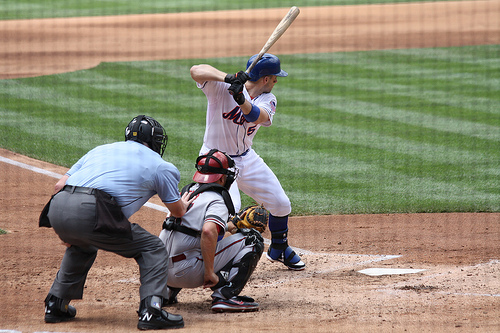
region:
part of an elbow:
[201, 230, 213, 246]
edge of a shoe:
[223, 265, 232, 276]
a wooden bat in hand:
[206, 0, 305, 100]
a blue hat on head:
[223, 40, 295, 86]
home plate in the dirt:
[311, 233, 445, 326]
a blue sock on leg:
[264, 182, 326, 279]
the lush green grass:
[281, 75, 426, 200]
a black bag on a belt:
[85, 183, 140, 245]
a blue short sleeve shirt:
[38, 140, 203, 215]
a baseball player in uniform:
[167, 18, 320, 229]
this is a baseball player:
[145, 10, 379, 295]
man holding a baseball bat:
[180, 0, 332, 119]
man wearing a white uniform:
[188, 36, 311, 258]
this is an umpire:
[25, 54, 208, 331]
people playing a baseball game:
[13, 7, 454, 322]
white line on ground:
[2, 114, 59, 202]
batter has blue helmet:
[234, 24, 292, 74]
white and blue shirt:
[209, 74, 292, 166]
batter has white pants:
[211, 167, 290, 220]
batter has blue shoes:
[266, 223, 301, 275]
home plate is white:
[375, 266, 420, 288]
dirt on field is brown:
[302, 181, 417, 287]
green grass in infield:
[325, 46, 477, 171]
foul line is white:
[3, 157, 67, 202]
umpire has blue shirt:
[75, 142, 184, 221]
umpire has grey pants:
[35, 220, 182, 326]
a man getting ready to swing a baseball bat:
[188, 0, 330, 266]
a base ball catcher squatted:
[155, 151, 285, 323]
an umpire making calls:
[39, 109, 195, 328]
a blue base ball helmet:
[227, 44, 292, 86]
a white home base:
[360, 248, 427, 289]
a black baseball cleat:
[213, 289, 279, 323]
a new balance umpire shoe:
[108, 297, 186, 326]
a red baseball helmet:
[201, 146, 231, 188]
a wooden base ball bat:
[244, 0, 304, 113]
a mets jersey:
[202, 72, 272, 172]